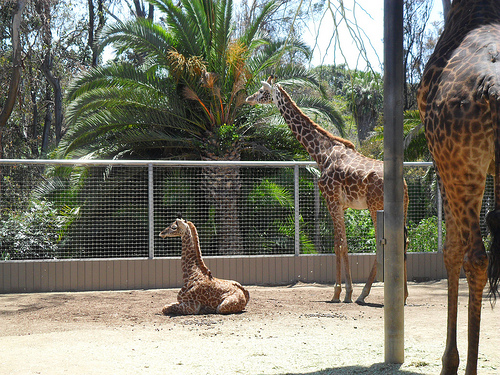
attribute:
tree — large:
[27, 4, 372, 254]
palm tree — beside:
[55, 1, 350, 256]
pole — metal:
[332, 26, 474, 326]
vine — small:
[323, 2, 350, 72]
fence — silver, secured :
[0, 160, 499, 286]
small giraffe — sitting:
[158, 215, 248, 317]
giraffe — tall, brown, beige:
[244, 74, 415, 306]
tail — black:
[481, 201, 498, 303]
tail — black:
[484, 139, 499, 311]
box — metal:
[374, 208, 389, 281]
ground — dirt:
[2, 278, 447, 373]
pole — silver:
[384, 1, 405, 361]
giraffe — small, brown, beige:
[152, 207, 252, 318]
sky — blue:
[350, 0, 373, 53]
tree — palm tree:
[55, 0, 351, 254]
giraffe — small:
[159, 219, 249, 312]